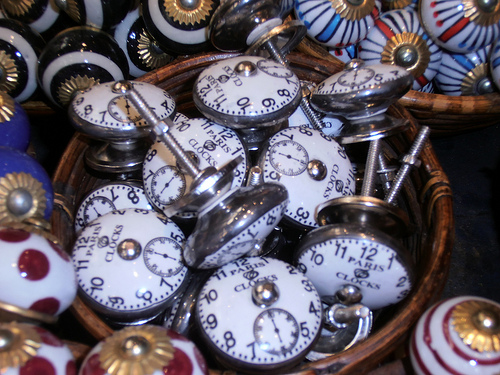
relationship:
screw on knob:
[120, 83, 252, 228] [119, 83, 292, 269]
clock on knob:
[70, 198, 199, 337] [68, 200, 200, 336]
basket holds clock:
[418, 180, 483, 295] [266, 137, 356, 220]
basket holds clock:
[418, 180, 483, 295] [154, 127, 243, 199]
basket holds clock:
[418, 180, 483, 295] [293, 243, 385, 303]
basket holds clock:
[418, 180, 483, 295] [197, 37, 275, 114]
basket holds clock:
[418, 180, 483, 295] [75, 218, 168, 293]